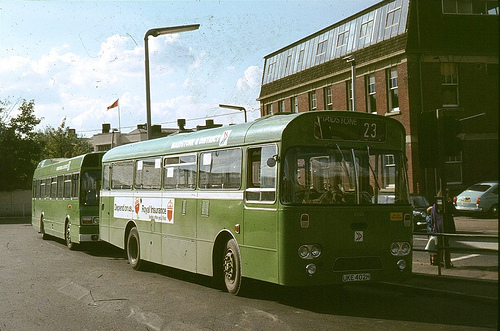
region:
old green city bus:
[20, 76, 437, 293]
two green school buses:
[27, 116, 440, 311]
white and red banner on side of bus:
[107, 186, 200, 234]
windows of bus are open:
[102, 149, 265, 206]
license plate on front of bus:
[335, 265, 394, 287]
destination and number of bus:
[307, 105, 394, 151]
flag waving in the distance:
[98, 75, 135, 131]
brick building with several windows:
[254, 12, 453, 208]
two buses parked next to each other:
[25, 105, 438, 305]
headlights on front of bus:
[296, 237, 434, 274]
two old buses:
[20, 104, 421, 289]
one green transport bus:
[94, 101, 433, 291]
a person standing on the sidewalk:
[423, 180, 464, 277]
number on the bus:
[318, 113, 396, 147]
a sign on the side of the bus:
[111, 193, 196, 233]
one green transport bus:
[21, 140, 98, 258]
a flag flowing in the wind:
[101, 88, 132, 130]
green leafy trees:
[0, 95, 79, 188]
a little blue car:
[445, 170, 499, 208]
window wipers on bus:
[318, 140, 412, 191]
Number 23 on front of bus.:
[360, 120, 387, 151]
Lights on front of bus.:
[291, 238, 423, 282]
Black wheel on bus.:
[216, 235, 258, 318]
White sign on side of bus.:
[106, 189, 211, 232]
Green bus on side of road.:
[95, 145, 407, 315]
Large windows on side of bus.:
[107, 158, 292, 195]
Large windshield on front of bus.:
[298, 143, 413, 200]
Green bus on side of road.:
[24, 151, 101, 263]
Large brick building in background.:
[281, 28, 449, 190]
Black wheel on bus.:
[123, 224, 143, 268]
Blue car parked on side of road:
[455, 179, 497, 216]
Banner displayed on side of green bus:
[110, 195, 175, 222]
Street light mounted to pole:
[142, 24, 204, 109]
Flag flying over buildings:
[105, 95, 127, 135]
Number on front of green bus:
[358, 117, 381, 143]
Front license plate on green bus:
[340, 270, 376, 285]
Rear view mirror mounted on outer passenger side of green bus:
[267, 147, 281, 179]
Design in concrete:
[59, 268, 129, 325]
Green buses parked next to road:
[30, 107, 423, 302]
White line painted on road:
[451, 253, 483, 263]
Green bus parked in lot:
[98, 108, 427, 296]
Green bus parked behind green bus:
[28, 150, 101, 249]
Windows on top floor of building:
[262, 12, 405, 83]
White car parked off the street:
[455, 181, 498, 217]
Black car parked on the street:
[407, 191, 432, 236]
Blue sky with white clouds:
[9, 59, 132, 106]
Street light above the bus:
[140, 20, 202, 139]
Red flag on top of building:
[102, 95, 123, 135]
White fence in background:
[2, 183, 29, 226]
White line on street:
[451, 251, 478, 263]